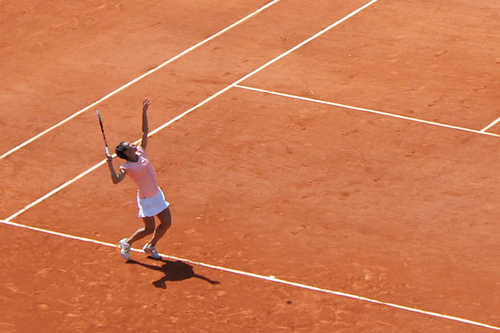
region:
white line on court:
[6, 99, 67, 173]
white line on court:
[156, 79, 213, 137]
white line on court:
[189, 235, 340, 330]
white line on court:
[236, 68, 494, 183]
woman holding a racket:
[90, 102, 140, 213]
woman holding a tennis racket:
[65, 79, 140, 194]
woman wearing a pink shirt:
[120, 151, 158, 209]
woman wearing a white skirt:
[132, 188, 180, 232]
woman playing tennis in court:
[77, 72, 205, 276]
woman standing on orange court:
[0, 11, 452, 331]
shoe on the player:
[113, 239, 134, 258]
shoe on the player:
[144, 243, 156, 260]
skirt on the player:
[135, 193, 170, 213]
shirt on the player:
[125, 155, 161, 190]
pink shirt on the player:
[125, 165, 160, 195]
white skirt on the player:
[132, 190, 167, 220]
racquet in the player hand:
[89, 105, 114, 158]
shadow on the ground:
[128, 250, 222, 285]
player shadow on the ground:
[124, 247, 219, 292]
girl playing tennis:
[70, 96, 180, 276]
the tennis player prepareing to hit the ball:
[92, 94, 187, 265]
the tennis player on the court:
[85, 92, 197, 270]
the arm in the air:
[136, 88, 166, 150]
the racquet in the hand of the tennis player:
[91, 108, 115, 165]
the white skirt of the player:
[133, 190, 173, 219]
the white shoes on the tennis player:
[111, 236, 164, 262]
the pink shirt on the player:
[121, 148, 166, 205]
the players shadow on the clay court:
[130, 253, 224, 297]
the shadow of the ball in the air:
[283, 288, 298, 313]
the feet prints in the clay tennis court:
[39, 280, 186, 332]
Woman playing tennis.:
[85, 96, 190, 267]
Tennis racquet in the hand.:
[85, 100, 120, 165]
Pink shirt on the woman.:
[90, 90, 170, 196]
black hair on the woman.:
[110, 136, 140, 158]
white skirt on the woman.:
[88, 93, 171, 221]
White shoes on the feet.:
[113, 235, 163, 262]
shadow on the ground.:
[118, 245, 218, 300]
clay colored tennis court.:
[0, 0, 495, 330]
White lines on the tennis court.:
[0, 0, 496, 330]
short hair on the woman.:
[109, 136, 139, 161]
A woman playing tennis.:
[34, 65, 249, 304]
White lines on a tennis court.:
[18, 13, 474, 332]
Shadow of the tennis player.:
[133, 256, 217, 298]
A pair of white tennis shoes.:
[115, 234, 167, 264]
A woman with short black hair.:
[107, 128, 144, 168]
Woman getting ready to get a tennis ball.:
[83, 83, 175, 269]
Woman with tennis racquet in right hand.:
[86, 103, 177, 205]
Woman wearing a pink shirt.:
[86, 102, 170, 196]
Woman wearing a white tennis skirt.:
[88, 126, 174, 224]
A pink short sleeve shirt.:
[106, 144, 163, 201]